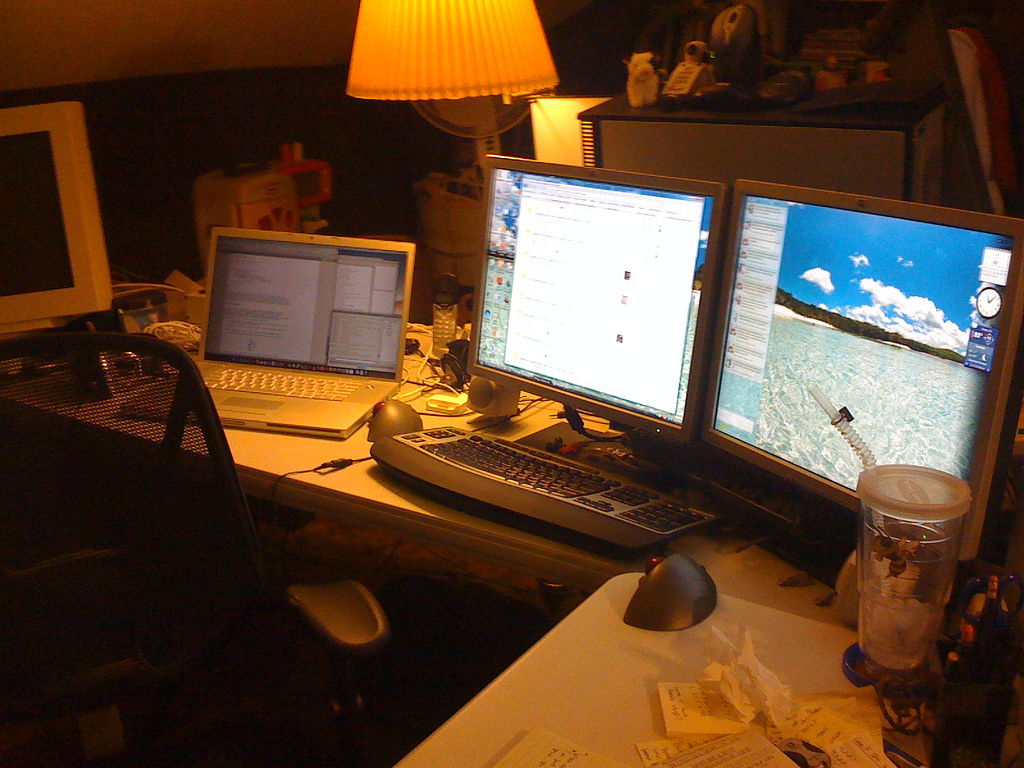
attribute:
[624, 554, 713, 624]
mouse — grey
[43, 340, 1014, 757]
desk — white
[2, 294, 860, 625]
desk — white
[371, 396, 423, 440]
mouse — grey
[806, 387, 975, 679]
cup — clear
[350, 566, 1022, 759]
desk — white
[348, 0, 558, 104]
shade — white, round, large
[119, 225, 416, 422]
laptop — large, silver, square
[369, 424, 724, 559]
keyboard — long, thin, black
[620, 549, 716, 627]
mouse — large, round, black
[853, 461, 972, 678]
cup — tall, clear, plastic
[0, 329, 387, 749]
chair — large, black, cloth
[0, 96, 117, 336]
screen — large, square, white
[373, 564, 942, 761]
table — white, square, large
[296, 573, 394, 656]
arm — thick, black, long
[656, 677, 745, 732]
paper — small, square, white